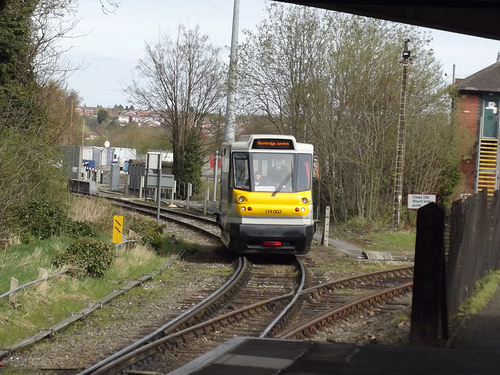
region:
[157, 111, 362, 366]
A train is on the tracks.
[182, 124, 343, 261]
The train is yellow and white.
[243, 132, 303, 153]
Lettering is on the train.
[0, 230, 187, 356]
Grass grows next to the tracks.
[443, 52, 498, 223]
A building is behind the tracks.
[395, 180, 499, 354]
A fence is next to the tracks.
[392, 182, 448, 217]
A sign is next to the building.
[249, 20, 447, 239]
Trees are behind the train.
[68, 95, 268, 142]
Buildings are in the background.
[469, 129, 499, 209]
The building has stairs.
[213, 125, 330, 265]
yellow and white rail car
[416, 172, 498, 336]
well worn wooden fence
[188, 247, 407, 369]
railroad track line junction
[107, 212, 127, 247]
bright yellow junction warning sign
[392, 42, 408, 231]
ladder leaning against utility pole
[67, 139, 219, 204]
utility buildings in the distance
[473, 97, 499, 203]
yellow stairway to second floor door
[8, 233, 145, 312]
leafy bush overgrowing guard rail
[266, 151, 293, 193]
engineer in small rail car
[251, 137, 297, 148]
sign showing rail car destination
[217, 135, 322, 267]
train engine on track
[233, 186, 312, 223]
yellow front of train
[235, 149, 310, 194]
windshield on front of train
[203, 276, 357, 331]
two sets of intersecting tracks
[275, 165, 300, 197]
wiper on train windshield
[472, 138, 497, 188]
yellow stairs on building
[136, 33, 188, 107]
branches with no leaves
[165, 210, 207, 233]
gravel in between tracks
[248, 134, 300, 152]
orange words on display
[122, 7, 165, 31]
cloud cover in daytime sky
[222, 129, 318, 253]
a white and yellow passenger train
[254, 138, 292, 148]
an electronic destination sign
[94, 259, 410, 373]
a set of train tracks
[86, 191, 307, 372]
a set of curved railroad tracks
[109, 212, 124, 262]
a yellow train sign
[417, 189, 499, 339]
a black wooden fence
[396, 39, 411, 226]
a tall train tower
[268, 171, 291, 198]
a train windshield wiper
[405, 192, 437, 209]
a white informational sign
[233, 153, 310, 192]
a train windshield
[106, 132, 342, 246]
trains on a track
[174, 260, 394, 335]
train tracks on the ground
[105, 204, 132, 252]
yellow train sign by tracks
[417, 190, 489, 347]
wooden fence by a track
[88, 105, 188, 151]
buildings in the background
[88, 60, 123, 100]
blue sky in the distance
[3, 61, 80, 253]
trees on side of the tracks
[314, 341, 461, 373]
shadow casted on the ground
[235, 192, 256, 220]
lights on front of train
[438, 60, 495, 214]
building on side of tracks